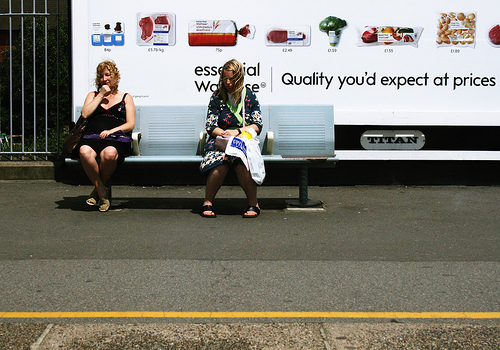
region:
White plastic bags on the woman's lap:
[222, 125, 270, 190]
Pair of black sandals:
[195, 200, 267, 220]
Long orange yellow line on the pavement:
[0, 306, 498, 323]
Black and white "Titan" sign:
[357, 130, 429, 150]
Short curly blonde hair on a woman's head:
[90, 60, 125, 92]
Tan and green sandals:
[77, 186, 116, 216]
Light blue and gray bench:
[58, 105, 336, 158]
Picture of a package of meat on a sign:
[259, 20, 317, 49]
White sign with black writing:
[190, 63, 498, 93]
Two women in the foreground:
[57, 38, 287, 224]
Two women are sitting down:
[55, 46, 282, 226]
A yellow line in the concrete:
[1, 304, 498, 338]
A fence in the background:
[3, 4, 75, 158]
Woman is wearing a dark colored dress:
[73, 77, 142, 161]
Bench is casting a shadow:
[32, 186, 322, 229]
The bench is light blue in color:
[63, 100, 341, 177]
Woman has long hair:
[206, 58, 253, 110]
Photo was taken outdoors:
[2, 5, 499, 348]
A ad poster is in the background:
[67, 3, 499, 148]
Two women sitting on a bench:
[77, 60, 261, 217]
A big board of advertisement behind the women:
[70, 0, 498, 157]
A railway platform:
[1, 180, 498, 349]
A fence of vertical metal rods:
[0, 1, 69, 159]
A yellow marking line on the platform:
[3, 310, 498, 317]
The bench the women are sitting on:
[64, 105, 334, 207]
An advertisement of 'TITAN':
[360, 129, 425, 150]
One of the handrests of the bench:
[266, 132, 273, 156]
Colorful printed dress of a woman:
[202, 85, 262, 165]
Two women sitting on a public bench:
[48, 54, 344, 239]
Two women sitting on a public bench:
[47, 50, 344, 225]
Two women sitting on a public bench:
[43, 55, 350, 230]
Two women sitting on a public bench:
[41, 53, 350, 223]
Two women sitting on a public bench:
[58, 54, 341, 221]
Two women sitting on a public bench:
[57, 57, 343, 225]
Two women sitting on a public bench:
[51, 57, 342, 217]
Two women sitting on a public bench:
[52, 56, 342, 223]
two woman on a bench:
[62, 57, 378, 233]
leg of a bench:
[291, 162, 319, 211]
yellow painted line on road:
[42, 284, 447, 344]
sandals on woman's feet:
[188, 196, 272, 221]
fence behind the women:
[6, 0, 63, 170]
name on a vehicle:
[356, 119, 426, 156]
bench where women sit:
[142, 99, 189, 166]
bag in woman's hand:
[226, 130, 269, 187]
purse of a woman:
[59, 121, 86, 157]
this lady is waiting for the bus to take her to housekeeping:
[200, 48, 272, 228]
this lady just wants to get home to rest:
[56, 39, 146, 222]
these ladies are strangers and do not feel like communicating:
[51, 46, 283, 226]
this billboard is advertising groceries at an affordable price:
[82, 12, 497, 124]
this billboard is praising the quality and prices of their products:
[77, 4, 499, 106]